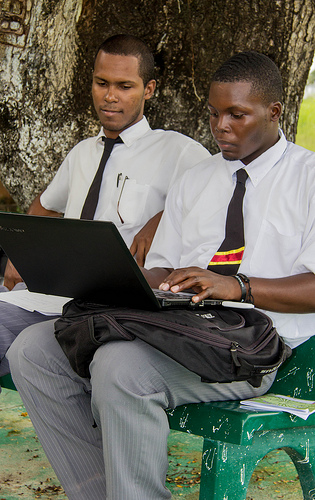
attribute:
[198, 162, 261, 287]
tie — yellow, red, black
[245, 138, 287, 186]
collar — white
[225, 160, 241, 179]
collar — white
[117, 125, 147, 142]
collar — white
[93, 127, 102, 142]
collar — white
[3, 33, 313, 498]
males — focused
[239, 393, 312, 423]
booklet — informative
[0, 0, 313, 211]
tree trunk — massive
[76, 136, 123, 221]
tie — black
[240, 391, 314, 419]
book — white, green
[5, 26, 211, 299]
guy — light colored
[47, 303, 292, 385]
bookbag — black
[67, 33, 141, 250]
man — sitting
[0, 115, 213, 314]
shirt — white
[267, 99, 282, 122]
left ear — dark colored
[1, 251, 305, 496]
bench — green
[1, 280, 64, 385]
slacks — gray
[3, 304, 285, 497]
slacks — gray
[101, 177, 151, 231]
pocket — breast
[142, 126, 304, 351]
shirt — white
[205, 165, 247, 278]
tie — red, yellow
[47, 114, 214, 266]
shirt — white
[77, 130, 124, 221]
tie — solid black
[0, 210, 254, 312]
laptop — black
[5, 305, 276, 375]
lap — guys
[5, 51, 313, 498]
guy — dark colored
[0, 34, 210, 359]
guy — light colored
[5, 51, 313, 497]
male — focused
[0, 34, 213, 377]
male — focused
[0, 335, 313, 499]
bench — green